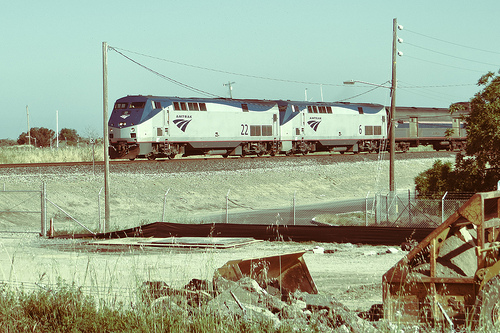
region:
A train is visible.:
[138, 74, 392, 182]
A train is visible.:
[174, 71, 289, 186]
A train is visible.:
[127, 44, 295, 214]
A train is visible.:
[68, 58, 449, 269]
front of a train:
[113, 99, 286, 155]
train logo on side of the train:
[169, 110, 196, 133]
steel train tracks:
[0, 154, 132, 181]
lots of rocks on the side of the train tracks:
[1, 161, 213, 199]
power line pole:
[363, 91, 416, 213]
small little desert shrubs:
[9, 265, 139, 332]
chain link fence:
[356, 190, 451, 225]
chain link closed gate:
[0, 182, 53, 235]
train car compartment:
[379, 105, 458, 147]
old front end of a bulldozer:
[212, 246, 327, 314]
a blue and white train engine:
[106, 92, 281, 157]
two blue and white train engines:
[107, 95, 388, 160]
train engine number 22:
[106, 93, 280, 155]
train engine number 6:
[275, 95, 387, 154]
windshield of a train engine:
[115, 99, 147, 111]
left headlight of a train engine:
[130, 133, 137, 140]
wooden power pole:
[101, 41, 112, 233]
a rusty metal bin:
[379, 192, 499, 331]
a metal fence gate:
[0, 180, 44, 237]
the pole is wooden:
[93, 41, 119, 230]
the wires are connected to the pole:
[110, 42, 202, 91]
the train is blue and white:
[111, 76, 381, 156]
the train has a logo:
[168, 111, 199, 131]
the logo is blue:
[171, 114, 216, 141]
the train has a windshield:
[113, 96, 146, 112]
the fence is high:
[7, 173, 84, 245]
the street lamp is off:
[336, 71, 410, 99]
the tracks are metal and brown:
[13, 149, 95, 173]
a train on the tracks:
[21, 76, 253, 171]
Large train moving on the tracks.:
[104, 95, 286, 172]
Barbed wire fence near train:
[371, 182, 470, 227]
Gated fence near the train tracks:
[3, 170, 88, 251]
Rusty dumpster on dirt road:
[372, 199, 498, 331]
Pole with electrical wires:
[79, 20, 121, 238]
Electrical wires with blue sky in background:
[385, 4, 498, 76]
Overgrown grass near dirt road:
[13, 280, 158, 332]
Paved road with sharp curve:
[230, 202, 345, 229]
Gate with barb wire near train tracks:
[0, 146, 53, 248]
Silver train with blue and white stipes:
[406, 99, 468, 159]